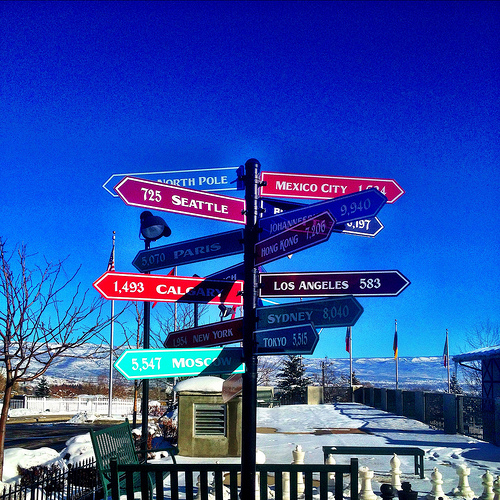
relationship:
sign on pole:
[116, 181, 241, 239] [234, 381, 279, 449]